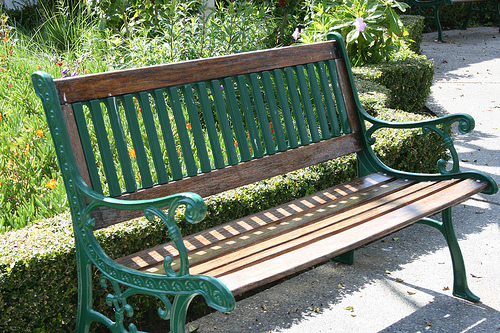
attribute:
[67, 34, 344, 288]
bench — brown, wooden, empty, green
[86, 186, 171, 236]
armrest — green, brown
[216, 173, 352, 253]
seat — wooden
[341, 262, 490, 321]
pavement — gray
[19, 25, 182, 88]
bushes — green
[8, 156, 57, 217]
grass — reflecting, green, tall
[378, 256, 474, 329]
shadow — fallen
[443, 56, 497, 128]
road — grey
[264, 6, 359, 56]
flowers — yellow, growing, pretty, behind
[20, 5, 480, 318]
picture — daytime, empty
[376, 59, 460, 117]
bush — green, manicured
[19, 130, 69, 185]
flower — orange, green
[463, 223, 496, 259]
floor — gray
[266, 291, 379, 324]
ground — reflecting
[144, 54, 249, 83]
wood — here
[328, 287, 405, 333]
leaves — dry, scattered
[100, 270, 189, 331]
legs — green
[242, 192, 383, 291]
slats — wooden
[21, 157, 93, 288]
shrubs — growing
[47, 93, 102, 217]
work — iron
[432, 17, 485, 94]
path — paved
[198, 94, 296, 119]
bars — blue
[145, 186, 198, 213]
railing — blue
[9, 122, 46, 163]
flowers — mulicolored